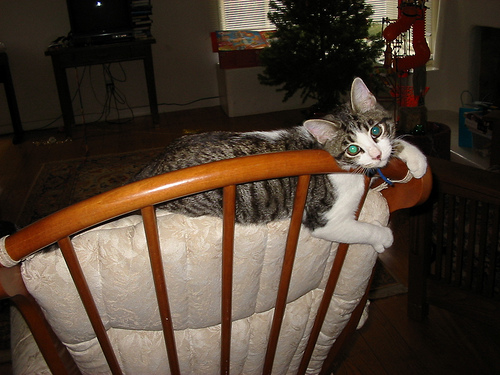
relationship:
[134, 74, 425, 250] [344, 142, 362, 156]
cat has eye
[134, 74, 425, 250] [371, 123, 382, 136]
cat has eye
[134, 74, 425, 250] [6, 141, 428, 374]
cat sitting on chair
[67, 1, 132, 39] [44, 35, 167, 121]
tv sitting on stand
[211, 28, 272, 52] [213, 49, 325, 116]
wrapped gift sitting on table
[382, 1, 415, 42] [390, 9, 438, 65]
stocking next to stocking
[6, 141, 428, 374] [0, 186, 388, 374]
chair has cushion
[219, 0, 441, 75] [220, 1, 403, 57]
window has mini blinds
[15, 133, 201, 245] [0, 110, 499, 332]
area rug on area rug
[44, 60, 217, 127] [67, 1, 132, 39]
cords hanging from tv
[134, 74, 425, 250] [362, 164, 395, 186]
cat has collar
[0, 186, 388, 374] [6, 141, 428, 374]
cushion sitting on chair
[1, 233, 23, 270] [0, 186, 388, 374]
strap attached to cushion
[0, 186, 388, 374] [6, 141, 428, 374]
cushion attached to chair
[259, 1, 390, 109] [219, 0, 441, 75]
christmas tree in front of window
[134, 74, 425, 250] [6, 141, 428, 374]
cat playing on chair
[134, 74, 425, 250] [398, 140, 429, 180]
cat has paw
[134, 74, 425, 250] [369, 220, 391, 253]
cat has paw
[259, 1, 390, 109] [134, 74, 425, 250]
christmas tree behind cat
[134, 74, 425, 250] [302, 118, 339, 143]
cat has ear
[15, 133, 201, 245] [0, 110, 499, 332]
area rug located on area rug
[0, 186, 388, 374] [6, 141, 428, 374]
cushion sits on chair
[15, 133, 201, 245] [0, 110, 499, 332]
area rug over area rug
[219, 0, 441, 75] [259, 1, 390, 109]
window behind christmas tree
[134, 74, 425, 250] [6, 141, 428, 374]
cat laying on chair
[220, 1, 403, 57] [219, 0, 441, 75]
mini blinds on window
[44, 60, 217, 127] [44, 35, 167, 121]
cords under stand